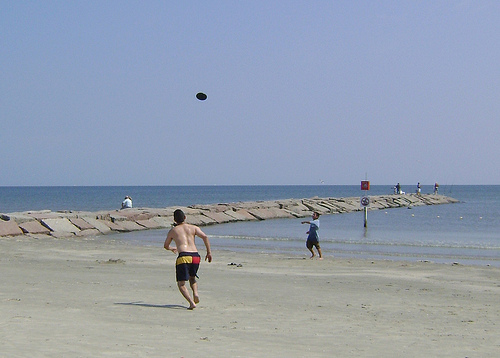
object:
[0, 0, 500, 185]
sky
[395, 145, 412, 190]
ground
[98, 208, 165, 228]
wall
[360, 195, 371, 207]
sign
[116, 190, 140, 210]
white shirt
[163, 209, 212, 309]
boy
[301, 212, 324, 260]
boy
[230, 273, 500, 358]
sand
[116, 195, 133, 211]
person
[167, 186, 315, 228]
structure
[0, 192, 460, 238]
pier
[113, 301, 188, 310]
shadow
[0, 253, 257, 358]
sand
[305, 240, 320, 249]
pants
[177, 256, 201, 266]
stripe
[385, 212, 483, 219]
line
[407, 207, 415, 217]
floaters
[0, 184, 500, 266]
water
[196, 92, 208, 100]
frisbee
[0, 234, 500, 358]
beach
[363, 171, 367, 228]
pole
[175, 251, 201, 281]
shorts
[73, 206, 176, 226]
rocks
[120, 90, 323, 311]
game